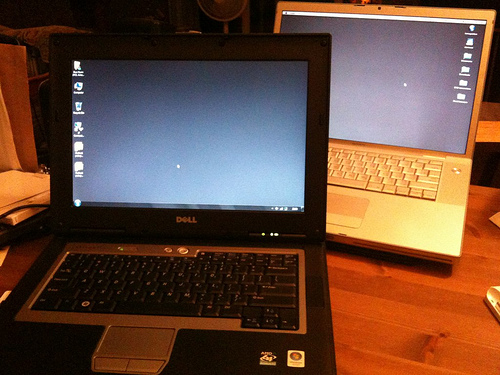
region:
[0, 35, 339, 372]
Black dell laptop on a table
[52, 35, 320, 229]
Desktop screen of a black Dell laptop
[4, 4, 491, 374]
Two laptops on a desk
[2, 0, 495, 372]
Two laptops with open screens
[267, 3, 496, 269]
Silver laptop on a table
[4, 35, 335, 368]
Black laptop with black keyboard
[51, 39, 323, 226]
Dell laptop screen with six program icons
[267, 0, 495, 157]
Laptop screen with six program icons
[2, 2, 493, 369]
Black laptop in front of a silver laptop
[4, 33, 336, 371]
Black laptop computer with active screen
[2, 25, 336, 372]
an open laptop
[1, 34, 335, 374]
the laptop is black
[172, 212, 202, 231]
a Dell symbol on the laptop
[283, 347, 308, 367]
a windows sticker on the laptop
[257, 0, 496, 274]
a silver computer behind the laptop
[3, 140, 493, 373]
the desk is wooden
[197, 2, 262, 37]
a fan behind the laptop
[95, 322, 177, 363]
a touchscreen on the laptop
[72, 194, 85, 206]
the start button on the screen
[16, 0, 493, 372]
a couple of computer on a desk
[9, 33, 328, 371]
a black computer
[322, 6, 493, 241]
a white computer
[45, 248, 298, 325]
key board on a computer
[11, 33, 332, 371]
black computer on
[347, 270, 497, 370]
a wooden desk top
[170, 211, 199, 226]
a name on a computer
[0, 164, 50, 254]
a stack of black and white disk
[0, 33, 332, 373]
a black laptop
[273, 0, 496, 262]
a silver laptop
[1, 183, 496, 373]
a brown wooden table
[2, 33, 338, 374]
a black dell laptop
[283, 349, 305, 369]
a microsoft windows tag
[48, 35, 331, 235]
an illuminated laptop monitor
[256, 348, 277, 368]
a black sticker with white writing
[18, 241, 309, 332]
a laptop key pad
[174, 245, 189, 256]
the power button on the laptop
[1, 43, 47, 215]
white colored papers behind the black computer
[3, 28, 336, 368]
black laptop on front of desk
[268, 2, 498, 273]
silver laptop on back of desk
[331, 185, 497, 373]
wooden desk with laptops on top of it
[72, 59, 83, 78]
logo on screen of black laptop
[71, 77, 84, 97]
internet logo on black laptop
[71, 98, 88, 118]
recycle bin logo on black laptop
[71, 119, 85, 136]
logo on black laptop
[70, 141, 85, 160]
logo on black laptop screen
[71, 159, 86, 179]
logo on black laptop screen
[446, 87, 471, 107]
logo on silver laptop screen